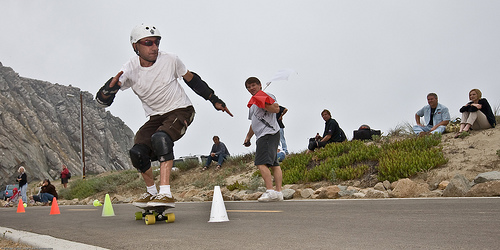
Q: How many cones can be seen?
A: Four.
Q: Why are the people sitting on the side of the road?
A: They are watching the skateboarder.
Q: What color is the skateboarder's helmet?
A: White.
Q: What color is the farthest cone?
A: Orange.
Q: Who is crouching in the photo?
A: The skateboarder.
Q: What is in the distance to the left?
A: Mountain.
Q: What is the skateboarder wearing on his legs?
A: Knee Pads.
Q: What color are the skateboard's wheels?
A: Yellow.